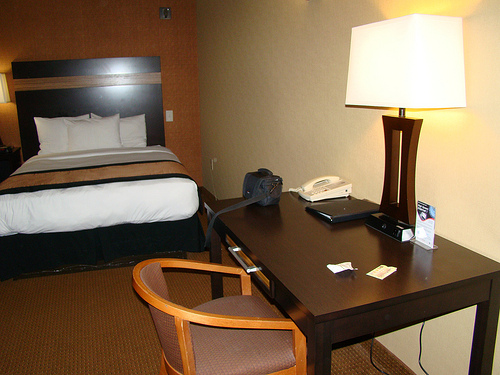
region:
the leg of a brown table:
[207, 224, 224, 297]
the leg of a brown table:
[303, 316, 331, 374]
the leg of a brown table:
[473, 269, 497, 374]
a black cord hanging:
[367, 315, 433, 373]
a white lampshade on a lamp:
[340, 13, 463, 113]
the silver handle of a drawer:
[231, 241, 261, 277]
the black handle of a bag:
[201, 186, 266, 248]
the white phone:
[300, 171, 352, 203]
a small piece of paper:
[326, 257, 353, 277]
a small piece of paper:
[366, 261, 393, 284]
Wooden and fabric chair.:
[129, 260, 244, 371]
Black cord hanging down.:
[412, 328, 424, 370]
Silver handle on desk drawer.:
[228, 247, 253, 275]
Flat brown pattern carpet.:
[36, 294, 103, 334]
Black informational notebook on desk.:
[309, 195, 377, 220]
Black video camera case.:
[240, 170, 281, 210]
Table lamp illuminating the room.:
[347, 17, 466, 187]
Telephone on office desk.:
[299, 173, 352, 200]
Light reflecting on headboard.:
[90, 66, 140, 98]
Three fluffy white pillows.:
[35, 116, 147, 151]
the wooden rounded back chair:
[131, 255, 305, 373]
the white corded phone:
[302, 171, 351, 203]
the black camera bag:
[204, 166, 282, 233]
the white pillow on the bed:
[30, 115, 93, 155]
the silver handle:
[225, 243, 258, 276]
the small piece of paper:
[325, 258, 356, 277]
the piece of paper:
[369, 261, 395, 286]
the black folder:
[306, 195, 380, 229]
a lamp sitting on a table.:
[341, 0, 470, 240]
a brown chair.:
[128, 253, 310, 373]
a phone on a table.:
[284, 165, 359, 212]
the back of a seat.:
[137, 259, 189, 371]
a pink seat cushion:
[173, 300, 296, 362]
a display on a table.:
[414, 194, 442, 249]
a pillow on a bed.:
[61, 108, 126, 162]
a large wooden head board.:
[6, 44, 173, 158]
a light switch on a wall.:
[165, 102, 178, 124]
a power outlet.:
[204, 150, 227, 176]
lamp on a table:
[342, 13, 465, 235]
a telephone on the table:
[288, 173, 350, 200]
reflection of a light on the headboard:
[94, 59, 139, 102]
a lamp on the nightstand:
[0, 67, 11, 104]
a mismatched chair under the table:
[134, 256, 307, 373]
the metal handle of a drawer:
[227, 245, 259, 273]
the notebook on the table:
[307, 199, 379, 221]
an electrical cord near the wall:
[417, 323, 427, 374]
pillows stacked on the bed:
[34, 113, 151, 156]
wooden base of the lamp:
[374, 117, 422, 232]